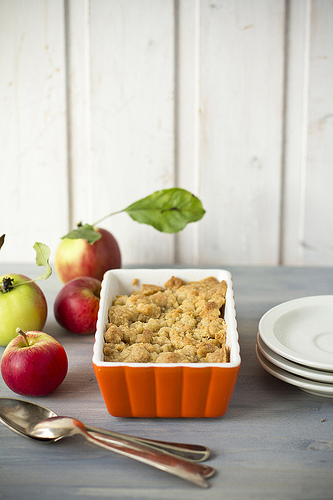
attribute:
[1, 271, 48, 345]
apple — green, red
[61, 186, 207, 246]
leaves — large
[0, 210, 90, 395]
apples — fresh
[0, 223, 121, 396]
fruit — red, green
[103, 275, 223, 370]
crust — crumbly, rounded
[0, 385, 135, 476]
spoon — silver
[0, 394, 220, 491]
spoon — silver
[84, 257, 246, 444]
container — orange, white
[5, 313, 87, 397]
apple — red, yellow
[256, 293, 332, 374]
plate — white, small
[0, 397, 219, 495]
spoons — silver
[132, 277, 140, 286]
crumb — stuck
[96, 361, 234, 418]
dish — orange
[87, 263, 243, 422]
pan — orange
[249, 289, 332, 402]
plates — white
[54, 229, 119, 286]
apple — red, yellow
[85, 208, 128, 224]
stem — long